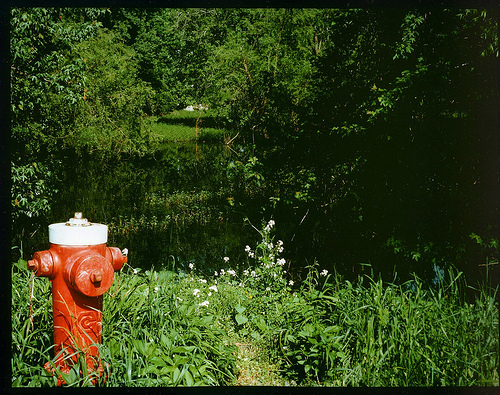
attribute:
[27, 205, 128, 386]
hydrant — red, white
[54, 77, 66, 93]
leaf — green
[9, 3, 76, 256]
tree — green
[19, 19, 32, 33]
leaf — green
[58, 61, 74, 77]
leaf — green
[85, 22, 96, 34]
leaf — green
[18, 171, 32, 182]
leaf — green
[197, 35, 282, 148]
tree — green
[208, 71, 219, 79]
leaf — green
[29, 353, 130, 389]
grass — green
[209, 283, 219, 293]
flower — white, wild, growing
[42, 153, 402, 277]
water — present, small, still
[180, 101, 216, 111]
building — white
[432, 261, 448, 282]
flower — blue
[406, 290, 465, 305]
grass — green, present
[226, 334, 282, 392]
trail — brown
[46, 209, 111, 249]
top — white, metal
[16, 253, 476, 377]
area — grassy